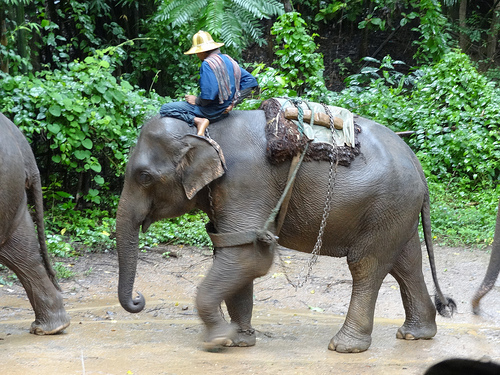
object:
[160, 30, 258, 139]
man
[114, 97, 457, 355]
elephant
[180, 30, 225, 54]
hat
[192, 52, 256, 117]
shirt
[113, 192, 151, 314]
trunk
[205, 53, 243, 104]
scarf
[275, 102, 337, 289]
chain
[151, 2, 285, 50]
tree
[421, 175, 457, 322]
tail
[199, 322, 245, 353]
paw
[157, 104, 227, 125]
pants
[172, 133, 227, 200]
ear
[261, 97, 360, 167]
blanket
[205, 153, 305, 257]
harness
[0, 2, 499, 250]
bushes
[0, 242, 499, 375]
mud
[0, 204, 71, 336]
leg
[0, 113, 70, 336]
elephant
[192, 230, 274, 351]
feet